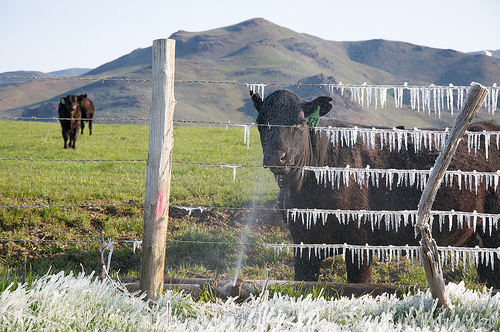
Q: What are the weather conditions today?
A: It is clear.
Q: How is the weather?
A: It is clear.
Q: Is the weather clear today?
A: Yes, it is clear.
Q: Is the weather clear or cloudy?
A: It is clear.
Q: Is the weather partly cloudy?
A: No, it is clear.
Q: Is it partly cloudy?
A: No, it is clear.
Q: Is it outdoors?
A: Yes, it is outdoors.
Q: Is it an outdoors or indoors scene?
A: It is outdoors.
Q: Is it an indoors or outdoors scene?
A: It is outdoors.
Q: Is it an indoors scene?
A: No, it is outdoors.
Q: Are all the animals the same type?
A: Yes, all the animals are cows.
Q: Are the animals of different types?
A: No, all the animals are cows.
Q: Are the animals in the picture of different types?
A: No, all the animals are cows.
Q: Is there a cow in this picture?
A: Yes, there is a cow.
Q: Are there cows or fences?
A: Yes, there is a cow.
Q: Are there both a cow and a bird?
A: No, there is a cow but no birds.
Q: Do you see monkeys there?
A: No, there are no monkeys.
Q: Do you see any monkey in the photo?
A: No, there are no monkeys.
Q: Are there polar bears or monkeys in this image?
A: No, there are no monkeys or polar bears.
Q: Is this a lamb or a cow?
A: This is a cow.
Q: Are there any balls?
A: No, there are no balls.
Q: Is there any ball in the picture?
A: No, there are no balls.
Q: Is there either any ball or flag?
A: No, there are no balls or flags.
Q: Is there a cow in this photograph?
A: Yes, there is a cow.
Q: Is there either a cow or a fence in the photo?
A: Yes, there is a cow.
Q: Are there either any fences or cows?
A: Yes, there is a cow.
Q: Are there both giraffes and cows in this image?
A: No, there is a cow but no giraffes.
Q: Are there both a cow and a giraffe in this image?
A: No, there is a cow but no giraffes.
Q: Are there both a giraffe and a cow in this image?
A: No, there is a cow but no giraffes.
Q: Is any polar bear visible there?
A: No, there are no polar bears.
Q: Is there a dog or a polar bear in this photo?
A: No, there are no polar bears or dogs.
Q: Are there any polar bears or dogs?
A: No, there are no polar bears or dogs.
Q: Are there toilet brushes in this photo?
A: No, there are no toilet brushes.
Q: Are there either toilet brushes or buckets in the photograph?
A: No, there are no toilet brushes or buckets.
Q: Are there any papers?
A: No, there are no papers.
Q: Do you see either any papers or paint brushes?
A: No, there are no papers or paint brushes.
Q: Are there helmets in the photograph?
A: No, there are no helmets.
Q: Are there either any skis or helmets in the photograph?
A: No, there are no helmets or skis.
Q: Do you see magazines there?
A: No, there are no magazines.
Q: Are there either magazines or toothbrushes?
A: No, there are no magazines or toothbrushes.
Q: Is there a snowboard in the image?
A: No, there are no snowboards.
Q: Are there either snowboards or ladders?
A: No, there are no snowboards or ladders.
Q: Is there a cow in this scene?
A: Yes, there is a cow.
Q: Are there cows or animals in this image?
A: Yes, there is a cow.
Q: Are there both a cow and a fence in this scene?
A: Yes, there are both a cow and a fence.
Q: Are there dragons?
A: No, there are no dragons.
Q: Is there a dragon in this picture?
A: No, there are no dragons.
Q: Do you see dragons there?
A: No, there are no dragons.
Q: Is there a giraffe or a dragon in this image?
A: No, there are no dragons or giraffes.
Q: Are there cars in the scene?
A: No, there are no cars.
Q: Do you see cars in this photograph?
A: No, there are no cars.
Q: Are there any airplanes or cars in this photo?
A: No, there are no cars or airplanes.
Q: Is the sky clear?
A: Yes, the sky is clear.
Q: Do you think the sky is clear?
A: Yes, the sky is clear.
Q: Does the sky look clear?
A: Yes, the sky is clear.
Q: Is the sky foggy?
A: No, the sky is clear.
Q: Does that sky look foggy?
A: No, the sky is clear.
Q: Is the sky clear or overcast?
A: The sky is clear.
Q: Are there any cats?
A: No, there are no cats.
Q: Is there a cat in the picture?
A: No, there are no cats.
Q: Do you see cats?
A: No, there are no cats.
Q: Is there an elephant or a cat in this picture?
A: No, there are no cats or elephants.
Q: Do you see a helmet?
A: No, there are no helmets.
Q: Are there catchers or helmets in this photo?
A: No, there are no helmets or catchers.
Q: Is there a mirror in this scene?
A: No, there are no mirrors.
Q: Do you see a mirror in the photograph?
A: No, there are no mirrors.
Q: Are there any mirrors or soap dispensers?
A: No, there are no mirrors or soap dispensers.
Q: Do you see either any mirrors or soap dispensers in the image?
A: No, there are no mirrors or soap dispensers.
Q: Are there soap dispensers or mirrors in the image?
A: No, there are no mirrors or soap dispensers.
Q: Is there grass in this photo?
A: Yes, there is grass.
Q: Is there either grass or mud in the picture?
A: Yes, there is grass.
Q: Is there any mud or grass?
A: Yes, there is grass.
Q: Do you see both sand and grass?
A: No, there is grass but no sand.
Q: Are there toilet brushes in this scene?
A: No, there are no toilet brushes.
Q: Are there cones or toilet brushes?
A: No, there are no toilet brushes or cones.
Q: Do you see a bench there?
A: No, there are no benches.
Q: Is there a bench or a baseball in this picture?
A: No, there are no benches or baseballs.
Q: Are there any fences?
A: Yes, there is a fence.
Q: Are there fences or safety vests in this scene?
A: Yes, there is a fence.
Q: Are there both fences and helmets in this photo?
A: No, there is a fence but no helmets.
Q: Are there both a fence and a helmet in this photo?
A: No, there is a fence but no helmets.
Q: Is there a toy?
A: No, there are no toys.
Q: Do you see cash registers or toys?
A: No, there are no toys or cash registers.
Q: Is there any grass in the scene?
A: Yes, there is grass.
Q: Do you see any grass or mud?
A: Yes, there is grass.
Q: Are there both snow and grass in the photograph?
A: No, there is grass but no snow.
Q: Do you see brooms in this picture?
A: No, there are no brooms.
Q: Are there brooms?
A: No, there are no brooms.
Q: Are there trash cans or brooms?
A: No, there are no brooms or trash cans.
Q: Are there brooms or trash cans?
A: No, there are no brooms or trash cans.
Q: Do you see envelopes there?
A: No, there are no envelopes.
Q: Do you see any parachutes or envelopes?
A: No, there are no envelopes or parachutes.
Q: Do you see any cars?
A: No, there are no cars.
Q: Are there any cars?
A: No, there are no cars.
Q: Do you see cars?
A: No, there are no cars.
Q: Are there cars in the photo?
A: No, there are no cars.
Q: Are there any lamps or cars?
A: No, there are no cars or lamps.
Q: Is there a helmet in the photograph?
A: No, there are no helmets.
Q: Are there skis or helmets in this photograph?
A: No, there are no helmets or skis.